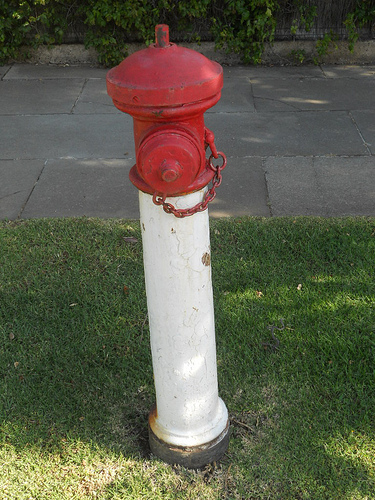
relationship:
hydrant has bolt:
[115, 15, 241, 457] [157, 158, 184, 183]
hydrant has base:
[115, 15, 241, 457] [142, 421, 242, 468]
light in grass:
[238, 285, 371, 314] [233, 225, 373, 434]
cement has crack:
[238, 81, 375, 210] [256, 154, 279, 223]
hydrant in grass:
[115, 15, 241, 457] [233, 225, 373, 434]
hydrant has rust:
[115, 15, 241, 457] [153, 25, 166, 52]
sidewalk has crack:
[238, 67, 371, 221] [256, 154, 279, 223]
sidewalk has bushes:
[238, 67, 371, 221] [2, 2, 372, 61]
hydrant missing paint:
[115, 15, 241, 457] [121, 21, 211, 185]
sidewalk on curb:
[238, 67, 371, 221] [2, 33, 374, 119]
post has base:
[136, 189, 235, 447] [142, 421, 242, 468]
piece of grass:
[16, 218, 30, 228] [233, 225, 373, 434]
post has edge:
[136, 189, 235, 447] [202, 195, 231, 334]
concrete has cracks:
[3, 70, 136, 208] [20, 156, 52, 229]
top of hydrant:
[102, 22, 226, 116] [115, 15, 241, 457]